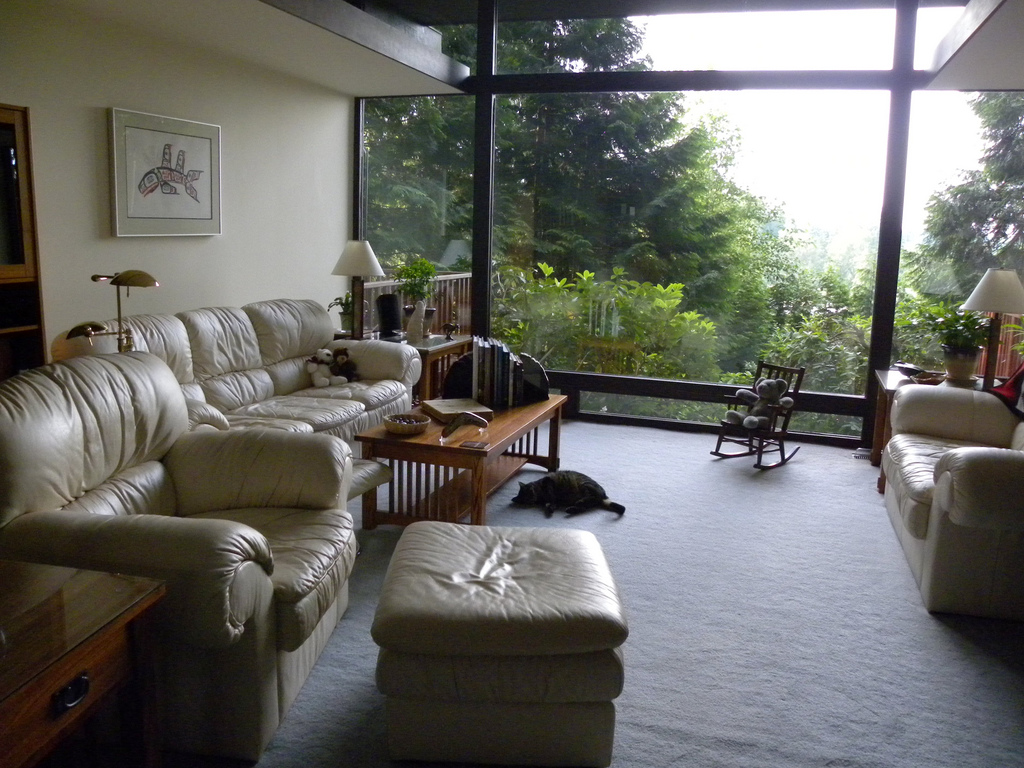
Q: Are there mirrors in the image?
A: No, there are no mirrors.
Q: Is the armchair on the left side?
A: Yes, the armchair is on the left of the image.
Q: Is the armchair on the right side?
A: No, the armchair is on the left of the image.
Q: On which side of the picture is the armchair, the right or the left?
A: The armchair is on the left of the image.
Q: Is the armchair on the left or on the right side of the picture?
A: The armchair is on the left of the image.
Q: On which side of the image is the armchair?
A: The armchair is on the left of the image.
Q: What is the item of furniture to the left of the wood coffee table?
A: The piece of furniture is an armchair.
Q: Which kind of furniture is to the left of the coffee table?
A: The piece of furniture is an armchair.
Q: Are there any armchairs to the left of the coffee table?
A: Yes, there is an armchair to the left of the coffee table.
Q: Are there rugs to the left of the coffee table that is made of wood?
A: No, there is an armchair to the left of the coffee table.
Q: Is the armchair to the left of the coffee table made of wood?
A: Yes, the armchair is to the left of the coffee table.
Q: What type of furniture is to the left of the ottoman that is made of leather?
A: The piece of furniture is an armchair.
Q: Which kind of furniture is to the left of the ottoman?
A: The piece of furniture is an armchair.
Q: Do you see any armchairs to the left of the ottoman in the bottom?
A: Yes, there is an armchair to the left of the ottoman.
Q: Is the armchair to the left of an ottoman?
A: Yes, the armchair is to the left of an ottoman.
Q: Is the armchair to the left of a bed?
A: No, the armchair is to the left of an ottoman.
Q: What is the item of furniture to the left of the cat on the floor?
A: The piece of furniture is an armchair.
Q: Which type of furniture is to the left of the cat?
A: The piece of furniture is an armchair.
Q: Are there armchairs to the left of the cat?
A: Yes, there is an armchair to the left of the cat.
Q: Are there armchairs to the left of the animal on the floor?
A: Yes, there is an armchair to the left of the cat.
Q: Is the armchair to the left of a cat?
A: Yes, the armchair is to the left of a cat.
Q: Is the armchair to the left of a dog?
A: No, the armchair is to the left of a cat.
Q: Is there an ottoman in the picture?
A: Yes, there is an ottoman.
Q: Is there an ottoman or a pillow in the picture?
A: Yes, there is an ottoman.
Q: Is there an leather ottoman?
A: Yes, there is an ottoman that is made of leather.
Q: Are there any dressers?
A: No, there are no dressers.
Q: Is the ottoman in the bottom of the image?
A: Yes, the ottoman is in the bottom of the image.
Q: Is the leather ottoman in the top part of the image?
A: No, the ottoman is in the bottom of the image.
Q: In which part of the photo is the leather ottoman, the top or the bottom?
A: The ottoman is in the bottom of the image.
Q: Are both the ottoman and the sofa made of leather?
A: Yes, both the ottoman and the sofa are made of leather.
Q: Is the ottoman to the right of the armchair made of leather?
A: Yes, the ottoman is made of leather.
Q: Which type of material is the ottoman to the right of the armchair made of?
A: The ottoman is made of leather.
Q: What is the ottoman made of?
A: The ottoman is made of leather.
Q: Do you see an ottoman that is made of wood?
A: No, there is an ottoman but it is made of leather.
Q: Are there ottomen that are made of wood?
A: No, there is an ottoman but it is made of leather.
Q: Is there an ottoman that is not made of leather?
A: No, there is an ottoman but it is made of leather.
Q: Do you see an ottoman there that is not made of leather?
A: No, there is an ottoman but it is made of leather.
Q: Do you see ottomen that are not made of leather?
A: No, there is an ottoman but it is made of leather.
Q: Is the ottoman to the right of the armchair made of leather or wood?
A: The ottoman is made of leather.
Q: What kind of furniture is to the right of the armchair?
A: The piece of furniture is an ottoman.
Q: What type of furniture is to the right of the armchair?
A: The piece of furniture is an ottoman.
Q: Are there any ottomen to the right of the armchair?
A: Yes, there is an ottoman to the right of the armchair.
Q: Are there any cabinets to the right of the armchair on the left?
A: No, there is an ottoman to the right of the armchair.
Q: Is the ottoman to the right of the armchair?
A: Yes, the ottoman is to the right of the armchair.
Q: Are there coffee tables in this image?
A: Yes, there is a coffee table.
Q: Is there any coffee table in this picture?
A: Yes, there is a coffee table.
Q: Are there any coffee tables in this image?
A: Yes, there is a coffee table.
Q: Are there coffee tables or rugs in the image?
A: Yes, there is a coffee table.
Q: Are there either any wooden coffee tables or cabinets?
A: Yes, there is a wood coffee table.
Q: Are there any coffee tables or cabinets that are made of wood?
A: Yes, the coffee table is made of wood.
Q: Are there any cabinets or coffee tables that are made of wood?
A: Yes, the coffee table is made of wood.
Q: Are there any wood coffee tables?
A: Yes, there is a wood coffee table.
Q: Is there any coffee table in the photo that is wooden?
A: Yes, there is a coffee table that is wooden.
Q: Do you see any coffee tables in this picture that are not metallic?
A: Yes, there is a wooden coffee table.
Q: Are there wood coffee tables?
A: Yes, there is a coffee table that is made of wood.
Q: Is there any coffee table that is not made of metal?
A: Yes, there is a coffee table that is made of wood.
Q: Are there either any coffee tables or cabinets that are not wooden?
A: No, there is a coffee table but it is wooden.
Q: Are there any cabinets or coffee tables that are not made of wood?
A: No, there is a coffee table but it is made of wood.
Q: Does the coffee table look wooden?
A: Yes, the coffee table is wooden.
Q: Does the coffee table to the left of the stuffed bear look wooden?
A: Yes, the coffee table is wooden.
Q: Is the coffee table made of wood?
A: Yes, the coffee table is made of wood.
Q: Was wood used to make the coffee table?
A: Yes, the coffee table is made of wood.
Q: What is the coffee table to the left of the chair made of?
A: The coffee table is made of wood.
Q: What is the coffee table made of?
A: The coffee table is made of wood.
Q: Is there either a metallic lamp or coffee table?
A: No, there is a coffee table but it is wooden.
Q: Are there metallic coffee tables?
A: No, there is a coffee table but it is wooden.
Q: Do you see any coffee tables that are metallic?
A: No, there is a coffee table but it is wooden.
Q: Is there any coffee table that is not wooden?
A: No, there is a coffee table but it is wooden.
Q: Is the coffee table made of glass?
A: No, the coffee table is made of wood.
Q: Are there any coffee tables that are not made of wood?
A: No, there is a coffee table but it is made of wood.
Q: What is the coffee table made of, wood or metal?
A: The coffee table is made of wood.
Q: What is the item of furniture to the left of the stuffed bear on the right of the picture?
A: The piece of furniture is a coffee table.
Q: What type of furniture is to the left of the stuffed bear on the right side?
A: The piece of furniture is a coffee table.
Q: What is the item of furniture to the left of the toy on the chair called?
A: The piece of furniture is a coffee table.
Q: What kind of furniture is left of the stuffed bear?
A: The piece of furniture is a coffee table.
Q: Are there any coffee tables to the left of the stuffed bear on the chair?
A: Yes, there is a coffee table to the left of the stuffed bear.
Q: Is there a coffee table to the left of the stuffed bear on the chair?
A: Yes, there is a coffee table to the left of the stuffed bear.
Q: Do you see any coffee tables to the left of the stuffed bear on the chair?
A: Yes, there is a coffee table to the left of the stuffed bear.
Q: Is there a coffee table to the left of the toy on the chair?
A: Yes, there is a coffee table to the left of the stuffed bear.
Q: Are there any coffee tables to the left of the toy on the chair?
A: Yes, there is a coffee table to the left of the stuffed bear.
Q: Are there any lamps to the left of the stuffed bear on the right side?
A: No, there is a coffee table to the left of the stuffed bear.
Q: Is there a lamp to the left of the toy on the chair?
A: No, there is a coffee table to the left of the stuffed bear.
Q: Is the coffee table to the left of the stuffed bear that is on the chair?
A: Yes, the coffee table is to the left of the stuffed bear.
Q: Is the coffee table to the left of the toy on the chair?
A: Yes, the coffee table is to the left of the stuffed bear.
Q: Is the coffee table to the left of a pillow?
A: No, the coffee table is to the left of the stuffed bear.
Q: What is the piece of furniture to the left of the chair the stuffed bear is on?
A: The piece of furniture is a coffee table.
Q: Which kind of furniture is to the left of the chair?
A: The piece of furniture is a coffee table.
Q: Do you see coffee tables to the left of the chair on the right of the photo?
A: Yes, there is a coffee table to the left of the chair.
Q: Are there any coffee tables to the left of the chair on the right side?
A: Yes, there is a coffee table to the left of the chair.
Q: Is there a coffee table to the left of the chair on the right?
A: Yes, there is a coffee table to the left of the chair.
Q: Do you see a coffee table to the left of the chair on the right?
A: Yes, there is a coffee table to the left of the chair.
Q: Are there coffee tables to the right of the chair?
A: No, the coffee table is to the left of the chair.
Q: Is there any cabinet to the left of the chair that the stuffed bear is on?
A: No, there is a coffee table to the left of the chair.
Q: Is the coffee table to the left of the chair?
A: Yes, the coffee table is to the left of the chair.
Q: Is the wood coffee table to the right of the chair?
A: No, the coffee table is to the left of the chair.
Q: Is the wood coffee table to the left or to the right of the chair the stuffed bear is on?
A: The coffee table is to the left of the chair.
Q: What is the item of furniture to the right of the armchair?
A: The piece of furniture is a coffee table.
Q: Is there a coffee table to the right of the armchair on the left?
A: Yes, there is a coffee table to the right of the armchair.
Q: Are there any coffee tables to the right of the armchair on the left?
A: Yes, there is a coffee table to the right of the armchair.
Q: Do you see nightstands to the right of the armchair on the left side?
A: No, there is a coffee table to the right of the armchair.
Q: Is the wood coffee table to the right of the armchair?
A: Yes, the coffee table is to the right of the armchair.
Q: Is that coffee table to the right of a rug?
A: No, the coffee table is to the right of the armchair.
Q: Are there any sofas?
A: Yes, there is a sofa.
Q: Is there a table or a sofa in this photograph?
A: Yes, there is a sofa.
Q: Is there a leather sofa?
A: Yes, there is a sofa that is made of leather.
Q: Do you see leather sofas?
A: Yes, there is a sofa that is made of leather.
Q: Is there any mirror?
A: No, there are no mirrors.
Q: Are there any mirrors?
A: No, there are no mirrors.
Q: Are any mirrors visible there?
A: No, there are no mirrors.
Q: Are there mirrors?
A: No, there are no mirrors.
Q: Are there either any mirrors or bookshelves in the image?
A: No, there are no mirrors or bookshelves.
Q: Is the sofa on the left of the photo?
A: Yes, the sofa is on the left of the image.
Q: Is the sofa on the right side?
A: No, the sofa is on the left of the image.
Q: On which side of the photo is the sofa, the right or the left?
A: The sofa is on the left of the image.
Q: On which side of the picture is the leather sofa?
A: The sofa is on the left of the image.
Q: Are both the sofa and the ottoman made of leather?
A: Yes, both the sofa and the ottoman are made of leather.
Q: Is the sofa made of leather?
A: Yes, the sofa is made of leather.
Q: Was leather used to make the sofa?
A: Yes, the sofa is made of leather.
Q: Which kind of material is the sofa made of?
A: The sofa is made of leather.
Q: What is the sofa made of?
A: The sofa is made of leather.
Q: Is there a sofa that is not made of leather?
A: No, there is a sofa but it is made of leather.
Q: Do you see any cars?
A: No, there are no cars.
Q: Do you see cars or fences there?
A: No, there are no cars or fences.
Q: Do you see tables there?
A: Yes, there is a table.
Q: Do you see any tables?
A: Yes, there is a table.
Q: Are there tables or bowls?
A: Yes, there is a table.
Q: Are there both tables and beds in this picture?
A: No, there is a table but no beds.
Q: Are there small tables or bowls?
A: Yes, there is a small table.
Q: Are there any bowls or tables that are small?
A: Yes, the table is small.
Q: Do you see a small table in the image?
A: Yes, there is a small table.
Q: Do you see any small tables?
A: Yes, there is a small table.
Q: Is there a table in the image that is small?
A: Yes, there is a table that is small.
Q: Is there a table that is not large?
A: Yes, there is a small table.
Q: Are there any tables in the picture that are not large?
A: Yes, there is a small table.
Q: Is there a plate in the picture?
A: No, there are no plates.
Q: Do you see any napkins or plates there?
A: No, there are no plates or napkins.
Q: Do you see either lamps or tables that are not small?
A: No, there is a table but it is small.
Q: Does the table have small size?
A: Yes, the table is small.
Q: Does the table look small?
A: Yes, the table is small.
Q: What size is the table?
A: The table is small.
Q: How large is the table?
A: The table is small.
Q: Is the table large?
A: No, the table is small.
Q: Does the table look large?
A: No, the table is small.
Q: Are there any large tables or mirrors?
A: No, there is a table but it is small.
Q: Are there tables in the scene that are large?
A: No, there is a table but it is small.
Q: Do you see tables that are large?
A: No, there is a table but it is small.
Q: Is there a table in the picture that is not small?
A: No, there is a table but it is small.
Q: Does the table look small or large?
A: The table is small.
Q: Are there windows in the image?
A: Yes, there is a window.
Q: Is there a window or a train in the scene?
A: Yes, there is a window.